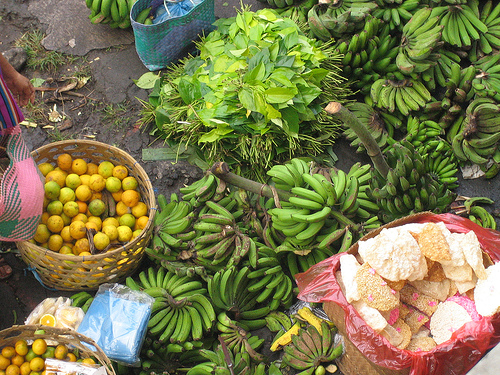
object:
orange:
[53, 342, 67, 361]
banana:
[435, 156, 450, 175]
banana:
[463, 196, 495, 214]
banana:
[321, 180, 338, 207]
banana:
[265, 170, 295, 186]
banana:
[301, 172, 328, 202]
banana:
[317, 226, 345, 250]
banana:
[335, 169, 346, 200]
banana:
[336, 226, 353, 256]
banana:
[294, 218, 325, 240]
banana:
[305, 205, 331, 224]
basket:
[12, 137, 158, 290]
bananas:
[288, 196, 324, 210]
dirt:
[46, 96, 147, 143]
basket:
[0, 323, 117, 374]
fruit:
[121, 189, 140, 208]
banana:
[320, 320, 331, 356]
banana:
[185, 292, 217, 323]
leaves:
[263, 86, 296, 105]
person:
[0, 49, 38, 282]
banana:
[297, 326, 318, 356]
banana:
[269, 321, 302, 352]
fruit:
[122, 176, 139, 191]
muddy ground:
[44, 60, 142, 131]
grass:
[13, 26, 65, 71]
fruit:
[65, 173, 82, 189]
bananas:
[184, 304, 203, 340]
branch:
[321, 101, 393, 182]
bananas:
[291, 333, 315, 359]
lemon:
[38, 313, 57, 328]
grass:
[96, 95, 143, 130]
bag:
[128, 0, 217, 72]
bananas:
[458, 10, 480, 41]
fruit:
[88, 173, 105, 192]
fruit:
[75, 184, 93, 202]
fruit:
[62, 201, 78, 217]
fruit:
[48, 233, 64, 251]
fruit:
[44, 180, 61, 199]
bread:
[356, 227, 428, 283]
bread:
[418, 222, 452, 262]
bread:
[457, 229, 490, 280]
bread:
[428, 300, 473, 346]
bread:
[357, 303, 389, 333]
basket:
[320, 210, 498, 375]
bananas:
[150, 307, 175, 335]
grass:
[43, 122, 72, 142]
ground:
[0, 0, 500, 375]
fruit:
[112, 164, 128, 179]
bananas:
[321, 179, 337, 206]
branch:
[210, 161, 297, 200]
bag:
[294, 211, 500, 375]